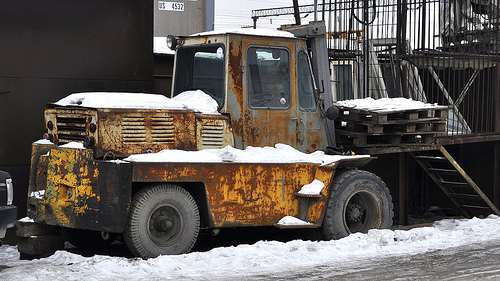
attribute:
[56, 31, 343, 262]
vehicle —  yellow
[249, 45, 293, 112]
window — loader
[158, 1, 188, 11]
white tag — numbered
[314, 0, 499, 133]
fence — black, metal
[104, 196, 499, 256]
street — snow covered, ice covered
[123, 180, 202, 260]
tractor tire — large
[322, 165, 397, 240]
tractor tire — large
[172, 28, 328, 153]
cab — driver's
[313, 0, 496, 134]
bars — metal